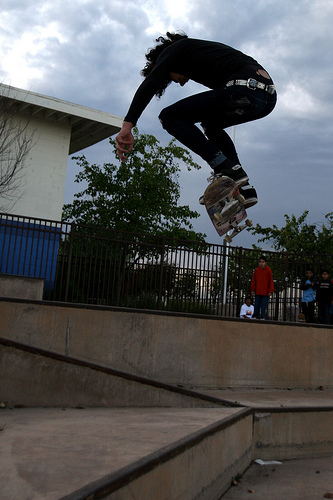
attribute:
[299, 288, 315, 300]
jacket — blue and black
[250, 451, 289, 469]
paper — white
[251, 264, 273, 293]
sweater — red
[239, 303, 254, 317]
top — white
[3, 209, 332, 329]
fence — black, wrought iron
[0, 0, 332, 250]
clouds — white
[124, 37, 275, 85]
black shirt — long sleeve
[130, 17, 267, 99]
shirt — white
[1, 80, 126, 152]
roof — white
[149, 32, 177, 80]
hair — curly, black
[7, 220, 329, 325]
iron fence — black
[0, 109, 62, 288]
building — white and blue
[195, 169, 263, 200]
feet — skateboarder's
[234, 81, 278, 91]
belt — white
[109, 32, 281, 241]
skateboarder — performing a trick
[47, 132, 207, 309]
trees — green 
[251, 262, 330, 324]
boys — close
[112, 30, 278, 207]
man — black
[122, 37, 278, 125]
shirt — long sleeve